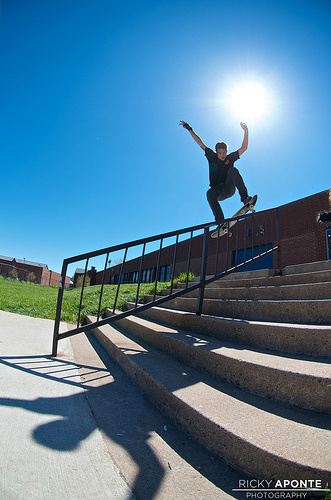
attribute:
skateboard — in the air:
[207, 191, 258, 241]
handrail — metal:
[52, 206, 286, 349]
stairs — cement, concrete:
[80, 260, 327, 499]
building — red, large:
[96, 186, 328, 285]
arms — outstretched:
[173, 113, 249, 158]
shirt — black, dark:
[202, 147, 240, 185]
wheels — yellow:
[245, 202, 257, 219]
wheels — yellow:
[223, 223, 233, 239]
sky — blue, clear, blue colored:
[2, 0, 330, 199]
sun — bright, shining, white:
[219, 71, 281, 129]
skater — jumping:
[178, 119, 257, 224]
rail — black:
[45, 206, 290, 364]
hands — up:
[178, 119, 252, 135]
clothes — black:
[201, 149, 258, 217]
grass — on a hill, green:
[0, 273, 197, 324]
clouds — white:
[6, 232, 126, 272]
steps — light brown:
[84, 253, 328, 498]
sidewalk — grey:
[0, 306, 258, 499]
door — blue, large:
[232, 240, 273, 270]